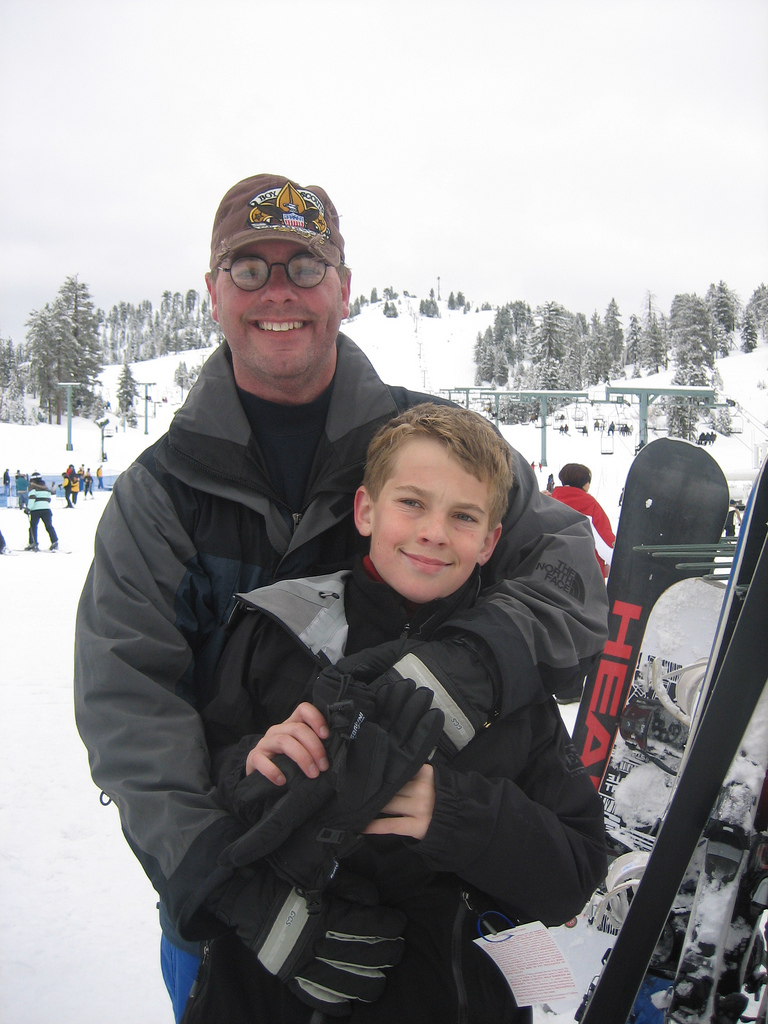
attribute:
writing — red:
[571, 595, 643, 799]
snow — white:
[475, 338, 489, 379]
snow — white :
[491, 346, 509, 390]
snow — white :
[644, 314, 664, 375]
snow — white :
[626, 311, 646, 377]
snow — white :
[600, 294, 624, 375]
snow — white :
[584, 308, 612, 386]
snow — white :
[733, 307, 756, 354]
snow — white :
[114, 359, 133, 414]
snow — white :
[528, 305, 564, 391]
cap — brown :
[200, 173, 347, 267]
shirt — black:
[240, 378, 342, 506]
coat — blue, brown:
[18, 479, 49, 511]